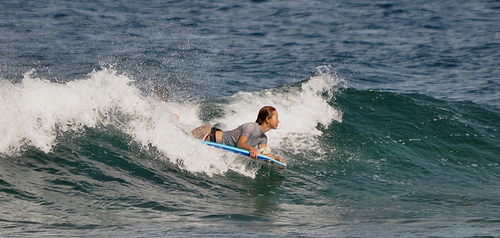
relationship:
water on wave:
[0, 2, 498, 235] [0, 59, 349, 190]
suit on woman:
[184, 118, 274, 155] [172, 91, 303, 168]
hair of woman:
[252, 92, 282, 126] [185, 99, 291, 176]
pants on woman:
[190, 115, 221, 143] [182, 99, 293, 171]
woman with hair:
[190, 103, 280, 160] [253, 97, 281, 131]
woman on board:
[190, 103, 280, 160] [195, 139, 289, 169]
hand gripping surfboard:
[240, 141, 261, 160] [190, 133, 290, 173]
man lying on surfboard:
[173, 105, 288, 169] [200, 137, 292, 177]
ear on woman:
[263, 111, 273, 122] [190, 103, 280, 160]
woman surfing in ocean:
[190, 103, 280, 160] [0, 0, 500, 237]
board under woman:
[195, 139, 289, 169] [183, 100, 280, 160]